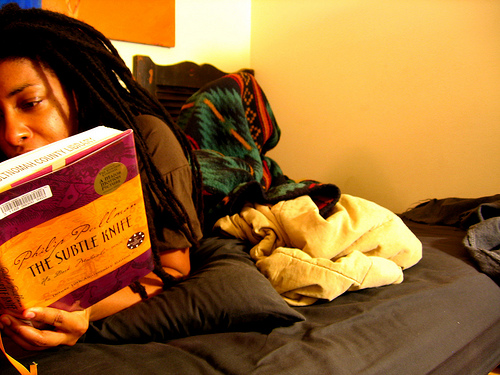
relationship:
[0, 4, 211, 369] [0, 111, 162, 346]
girl reads book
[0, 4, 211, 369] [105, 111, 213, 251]
girl has brown t-shirt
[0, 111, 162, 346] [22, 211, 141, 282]
book title "the subtle knife"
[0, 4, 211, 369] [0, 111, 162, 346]
woman reads book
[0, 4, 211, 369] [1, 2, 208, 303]
woman has dread-locks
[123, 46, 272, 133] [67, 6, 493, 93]
chair in background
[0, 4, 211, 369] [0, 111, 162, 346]
girl holds book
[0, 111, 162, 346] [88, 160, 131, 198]
book has sticker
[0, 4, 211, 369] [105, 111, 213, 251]
girl wears brown shirt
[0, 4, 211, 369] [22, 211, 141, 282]
girl reads "the subtle knife'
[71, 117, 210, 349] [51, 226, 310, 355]
arm rests on pillow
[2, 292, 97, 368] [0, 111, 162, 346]
fingers hold up book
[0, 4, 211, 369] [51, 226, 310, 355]
girl lays on dark pillow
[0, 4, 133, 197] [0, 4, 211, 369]
girl head with dread locks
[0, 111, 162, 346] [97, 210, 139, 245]
book has word knife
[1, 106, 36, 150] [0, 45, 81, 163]
nose on face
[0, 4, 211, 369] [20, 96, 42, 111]
girl has eyeball